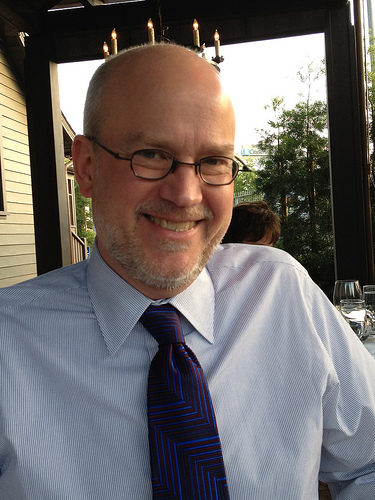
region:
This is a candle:
[208, 28, 229, 66]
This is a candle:
[187, 11, 204, 51]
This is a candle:
[142, 11, 163, 48]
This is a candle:
[109, 27, 122, 54]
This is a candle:
[98, 38, 109, 60]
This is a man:
[2, 38, 373, 494]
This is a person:
[6, 38, 363, 495]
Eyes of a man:
[117, 133, 255, 190]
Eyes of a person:
[125, 132, 268, 194]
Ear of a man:
[63, 116, 101, 218]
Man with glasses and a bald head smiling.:
[0, 41, 372, 495]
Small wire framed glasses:
[84, 128, 247, 196]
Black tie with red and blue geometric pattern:
[140, 304, 246, 499]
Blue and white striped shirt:
[9, 242, 365, 499]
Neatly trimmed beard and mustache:
[79, 185, 262, 310]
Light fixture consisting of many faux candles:
[90, 12, 245, 70]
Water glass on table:
[333, 294, 372, 347]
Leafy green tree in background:
[252, 78, 350, 291]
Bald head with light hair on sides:
[53, 40, 268, 176]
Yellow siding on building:
[2, 27, 79, 284]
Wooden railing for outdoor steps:
[70, 225, 93, 269]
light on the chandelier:
[95, 41, 113, 61]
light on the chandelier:
[142, 14, 163, 46]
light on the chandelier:
[188, 14, 200, 47]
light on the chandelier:
[210, 28, 227, 61]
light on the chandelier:
[105, 27, 132, 53]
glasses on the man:
[125, 151, 233, 191]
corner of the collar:
[176, 304, 214, 344]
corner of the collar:
[85, 331, 126, 364]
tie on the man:
[130, 316, 224, 497]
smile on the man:
[140, 208, 197, 239]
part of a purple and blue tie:
[129, 306, 232, 498]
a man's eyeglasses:
[84, 132, 250, 190]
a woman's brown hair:
[220, 197, 283, 245]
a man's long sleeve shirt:
[0, 238, 373, 498]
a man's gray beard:
[83, 199, 224, 289]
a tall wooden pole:
[23, 50, 73, 275]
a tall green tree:
[253, 92, 342, 289]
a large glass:
[332, 276, 360, 311]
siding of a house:
[0, 68, 44, 288]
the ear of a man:
[66, 128, 100, 200]